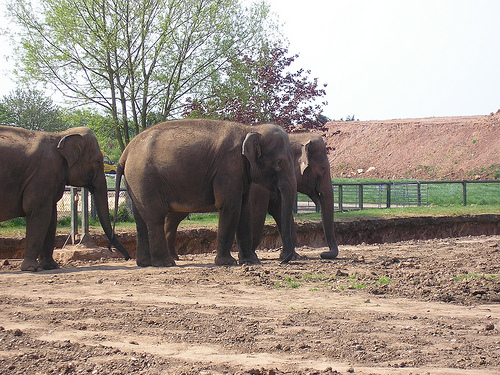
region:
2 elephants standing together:
[134, 107, 349, 277]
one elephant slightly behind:
[2, 118, 138, 270]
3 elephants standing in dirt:
[6, 230, 498, 372]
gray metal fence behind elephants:
[333, 180, 498, 206]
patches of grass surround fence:
[49, 176, 499, 222]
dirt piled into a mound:
[291, 116, 499, 178]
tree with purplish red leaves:
[247, 45, 329, 158]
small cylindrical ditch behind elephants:
[0, 202, 499, 260]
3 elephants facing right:
[2, 120, 352, 273]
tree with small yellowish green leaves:
[18, 0, 273, 171]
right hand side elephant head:
[290, 128, 341, 265]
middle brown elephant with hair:
[117, 110, 297, 272]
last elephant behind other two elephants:
[1, 118, 133, 295]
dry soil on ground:
[106, 269, 431, 366]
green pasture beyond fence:
[337, 177, 482, 215]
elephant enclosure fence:
[337, 174, 494, 230]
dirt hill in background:
[338, 112, 498, 171]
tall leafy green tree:
[49, 8, 233, 106]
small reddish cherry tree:
[211, 53, 321, 115]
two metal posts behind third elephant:
[62, 184, 97, 267]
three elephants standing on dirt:
[11, 114, 339, 279]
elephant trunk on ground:
[312, 215, 343, 267]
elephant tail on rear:
[105, 153, 127, 219]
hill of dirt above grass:
[371, 116, 464, 193]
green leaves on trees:
[50, 6, 100, 55]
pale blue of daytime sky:
[412, 21, 487, 84]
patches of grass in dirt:
[280, 267, 388, 297]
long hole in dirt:
[347, 211, 492, 254]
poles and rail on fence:
[375, 172, 476, 212]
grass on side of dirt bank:
[403, 203, 465, 225]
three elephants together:
[36, 75, 475, 292]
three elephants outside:
[43, 84, 418, 371]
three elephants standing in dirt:
[19, 63, 465, 335]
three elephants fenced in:
[24, 75, 370, 300]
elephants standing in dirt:
[29, 38, 495, 355]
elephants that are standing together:
[45, 40, 310, 230]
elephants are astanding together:
[55, 70, 445, 365]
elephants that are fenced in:
[40, 45, 480, 365]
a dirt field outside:
[180, 265, 460, 370]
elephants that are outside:
[39, 61, 411, 296]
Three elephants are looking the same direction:
[3, 112, 354, 278]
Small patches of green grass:
[273, 255, 393, 299]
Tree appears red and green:
[181, 52, 343, 147]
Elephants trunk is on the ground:
[299, 227, 348, 270]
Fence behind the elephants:
[41, 172, 498, 215]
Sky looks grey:
[5, 7, 492, 120]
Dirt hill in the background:
[270, 105, 497, 192]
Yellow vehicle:
[86, 145, 122, 176]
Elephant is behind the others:
[2, 109, 126, 280]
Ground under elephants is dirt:
[6, 234, 498, 372]